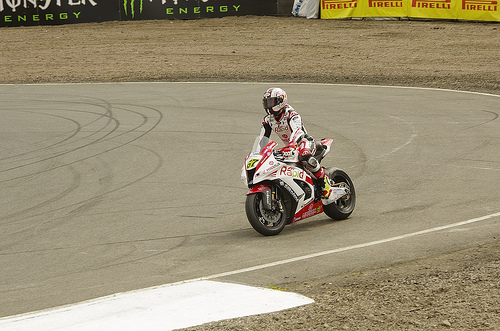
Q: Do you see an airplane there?
A: No, there are no airplanes.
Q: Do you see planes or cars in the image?
A: No, there are no planes or cars.